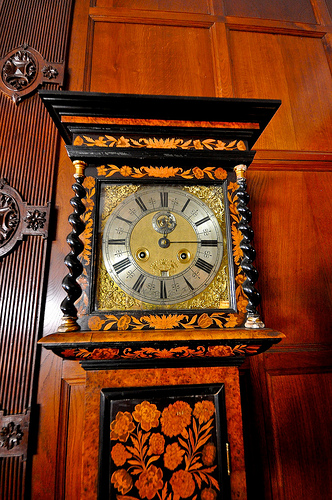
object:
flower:
[132, 400, 162, 433]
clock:
[94, 185, 231, 309]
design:
[109, 392, 226, 499]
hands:
[169, 240, 224, 246]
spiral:
[57, 181, 90, 319]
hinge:
[18, 411, 34, 462]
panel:
[228, 29, 332, 150]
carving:
[60, 345, 261, 361]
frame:
[89, 6, 212, 30]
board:
[32, 90, 285, 146]